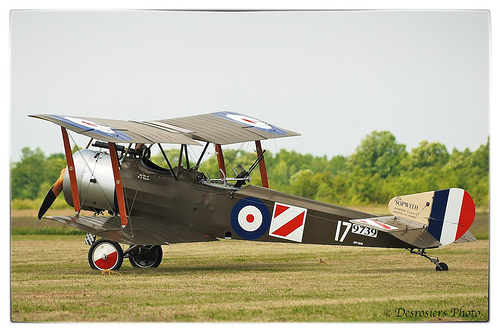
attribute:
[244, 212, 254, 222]
dot — red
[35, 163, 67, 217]
perpeller — orange, black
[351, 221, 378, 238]
number — black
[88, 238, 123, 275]
wheel — red, white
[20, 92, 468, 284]
plane — old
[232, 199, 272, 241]
ring — blue, white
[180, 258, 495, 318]
grass — green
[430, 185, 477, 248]
stripes — red, white, blue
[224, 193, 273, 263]
target — blue, white, red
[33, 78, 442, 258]
airplane — old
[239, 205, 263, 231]
ring — white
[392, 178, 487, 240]
stripes — red, white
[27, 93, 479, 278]
airplane — old